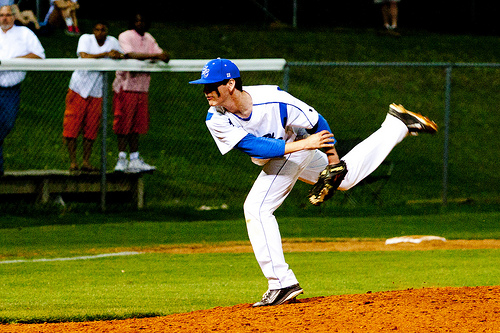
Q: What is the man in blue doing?
A: Throwing a ball.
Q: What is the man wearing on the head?
A: A blue cap.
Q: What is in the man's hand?
A: A glove.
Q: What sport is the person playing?
A: Baseball.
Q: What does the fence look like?
A: Green.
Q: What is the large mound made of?
A: Dirt.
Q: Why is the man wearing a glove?
A: He is playing baseball.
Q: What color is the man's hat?
A: Blue.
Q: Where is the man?
A: Pitcher's mound.